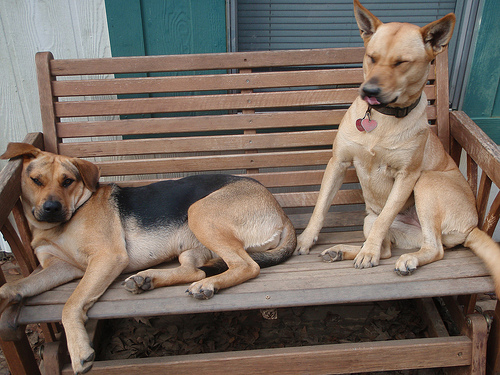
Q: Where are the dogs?
A: On a bench.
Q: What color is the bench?
A: Brown.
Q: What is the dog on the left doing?
A: Laying down.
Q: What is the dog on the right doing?
A: Sitting up.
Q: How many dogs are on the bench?
A: 2.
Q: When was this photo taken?
A: During the day.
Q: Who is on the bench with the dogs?
A: No one.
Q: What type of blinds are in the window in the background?
A: Horizontal.